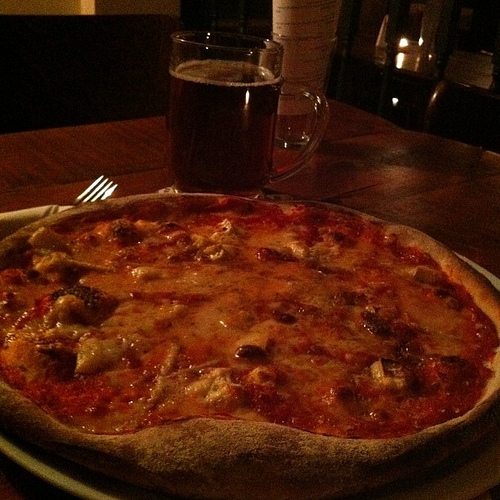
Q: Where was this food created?
A: Italy.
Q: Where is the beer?
A: In the mug.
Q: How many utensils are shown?
A: 1.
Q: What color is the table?
A: Brown.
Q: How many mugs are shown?
A: 1.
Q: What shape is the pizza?
A: Circle.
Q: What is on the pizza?
A: Cheese.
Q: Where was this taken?
A: Restaurant.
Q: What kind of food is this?
A: Pizza.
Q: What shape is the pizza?
A: Round.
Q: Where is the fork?
A: Next to the pizza.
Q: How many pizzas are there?
A: 1.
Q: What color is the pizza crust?
A: Brown.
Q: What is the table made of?
A: Wood.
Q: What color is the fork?
A: Silver.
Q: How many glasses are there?
A: 2.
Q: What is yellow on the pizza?
A: Cheese.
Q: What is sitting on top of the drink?
A: Foam.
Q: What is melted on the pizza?
A: Cheese.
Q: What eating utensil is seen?
A: Fork.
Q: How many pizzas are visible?
A: One.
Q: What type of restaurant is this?
A: A sit down restaurant.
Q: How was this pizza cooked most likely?
A: In a brick pizza oven.